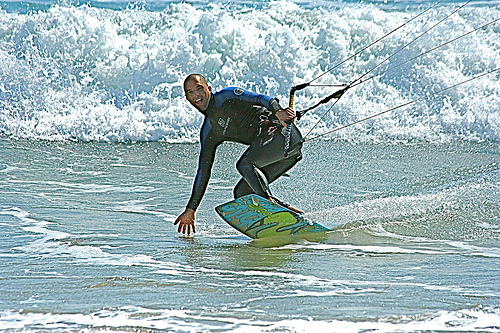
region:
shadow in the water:
[176, 229, 382, 304]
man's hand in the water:
[148, 191, 270, 255]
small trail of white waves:
[128, 245, 359, 307]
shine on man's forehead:
[165, 61, 214, 85]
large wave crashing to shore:
[21, 7, 274, 79]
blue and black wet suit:
[188, 105, 348, 169]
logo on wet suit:
[229, 84, 259, 104]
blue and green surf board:
[207, 185, 362, 267]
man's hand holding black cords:
[274, 62, 383, 181]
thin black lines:
[332, 35, 439, 119]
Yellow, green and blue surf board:
[211, 192, 347, 259]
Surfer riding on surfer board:
[155, 54, 317, 266]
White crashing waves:
[12, 5, 491, 142]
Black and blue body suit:
[182, 83, 299, 206]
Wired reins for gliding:
[276, 2, 498, 137]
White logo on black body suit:
[212, 109, 246, 140]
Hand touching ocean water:
[149, 201, 208, 247]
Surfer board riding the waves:
[210, 194, 348, 266]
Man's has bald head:
[178, 69, 210, 89]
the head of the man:
[181, 70, 214, 110]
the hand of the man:
[172, 203, 199, 238]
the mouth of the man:
[193, 96, 205, 105]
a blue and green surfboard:
[214, 190, 332, 242]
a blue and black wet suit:
[183, 84, 305, 210]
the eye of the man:
[196, 82, 203, 90]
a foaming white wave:
[1, 0, 499, 151]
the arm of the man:
[183, 125, 225, 210]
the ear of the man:
[205, 82, 214, 94]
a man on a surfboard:
[168, 68, 341, 252]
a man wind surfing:
[152, 41, 438, 275]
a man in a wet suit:
[176, 59, 286, 199]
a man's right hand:
[171, 202, 217, 256]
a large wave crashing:
[1, 7, 492, 142]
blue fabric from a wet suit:
[211, 83, 275, 111]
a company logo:
[216, 110, 235, 137]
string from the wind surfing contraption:
[302, 2, 499, 154]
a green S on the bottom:
[247, 210, 304, 255]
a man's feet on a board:
[252, 189, 313, 229]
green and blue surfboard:
[213, 193, 328, 243]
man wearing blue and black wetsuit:
[185, 83, 307, 210]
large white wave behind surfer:
[1, 1, 499, 141]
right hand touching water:
[172, 207, 198, 236]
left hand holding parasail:
[275, 107, 296, 125]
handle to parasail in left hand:
[283, 80, 298, 155]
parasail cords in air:
[289, 0, 498, 151]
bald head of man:
[181, 72, 206, 87]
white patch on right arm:
[231, 85, 245, 97]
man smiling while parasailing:
[173, 72, 305, 237]